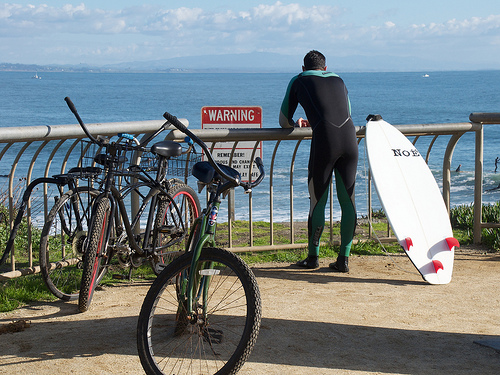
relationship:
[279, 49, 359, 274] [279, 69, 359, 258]
man wearing wetsuit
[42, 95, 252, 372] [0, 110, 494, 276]
bikes parked along railing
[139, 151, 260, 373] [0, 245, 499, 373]
bike parked on ground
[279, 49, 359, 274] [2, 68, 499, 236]
man looking at ocean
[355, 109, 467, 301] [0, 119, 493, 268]
surfboard leaning on railing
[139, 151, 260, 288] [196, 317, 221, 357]
bike resting on kickstand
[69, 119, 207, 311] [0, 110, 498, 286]
bike against fence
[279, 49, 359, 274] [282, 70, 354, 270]
man wearing wet suit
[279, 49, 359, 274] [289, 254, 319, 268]
man wearing black shoe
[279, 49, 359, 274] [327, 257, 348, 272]
man wearing black shoe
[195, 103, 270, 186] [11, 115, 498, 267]
sign on fence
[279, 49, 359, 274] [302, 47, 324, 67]
man with hair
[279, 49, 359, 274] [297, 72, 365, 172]
man wearing wetsuit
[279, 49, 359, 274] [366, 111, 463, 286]
man standing next to surfboard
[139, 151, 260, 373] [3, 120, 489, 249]
bike near railing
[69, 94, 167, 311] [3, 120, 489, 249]
bike near railing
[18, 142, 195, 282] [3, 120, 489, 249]
bike near railing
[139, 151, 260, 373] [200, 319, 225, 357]
bike propped on kickstand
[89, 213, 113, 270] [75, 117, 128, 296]
wheel on bike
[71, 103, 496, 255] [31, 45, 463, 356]
railing on beach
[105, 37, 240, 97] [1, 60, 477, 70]
mountains above shore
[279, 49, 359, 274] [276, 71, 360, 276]
man in a wet suit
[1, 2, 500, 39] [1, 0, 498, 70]
cloud in sky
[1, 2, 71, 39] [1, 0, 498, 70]
cloud in sky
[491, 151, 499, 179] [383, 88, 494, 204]
surfer in water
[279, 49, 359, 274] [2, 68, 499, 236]
man looking out to ocean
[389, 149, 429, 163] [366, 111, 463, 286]
letters on surfboard